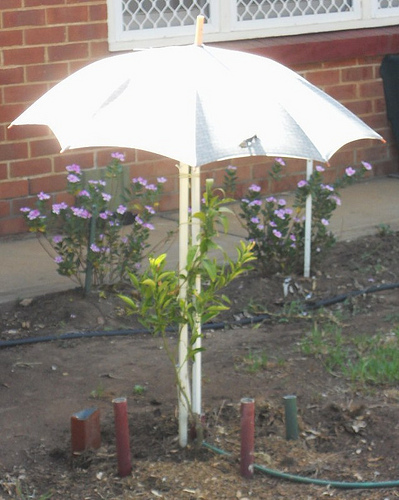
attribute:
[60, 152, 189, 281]
flowers — purple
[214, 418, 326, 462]
hose — attached, watering, black, rubber, green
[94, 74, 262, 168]
umbrella — white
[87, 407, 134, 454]
pole — white, supporting, red, green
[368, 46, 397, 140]
pail — black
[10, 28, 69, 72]
wall — brick, behind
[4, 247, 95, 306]
sidewalk — cement, gray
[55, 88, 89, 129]
canopy — white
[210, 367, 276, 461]
post — red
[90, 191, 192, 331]
plant — growing, under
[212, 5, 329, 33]
window — white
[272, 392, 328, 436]
pipe — green, red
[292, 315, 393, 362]
grass — green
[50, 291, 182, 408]
shade — plant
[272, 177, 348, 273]
stakes — green, white, around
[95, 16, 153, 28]
lattic — work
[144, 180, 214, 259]
poles — under, multiple